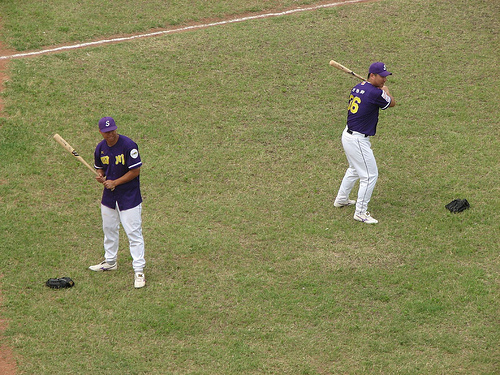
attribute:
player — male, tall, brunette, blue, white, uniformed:
[311, 52, 444, 270]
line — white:
[123, 20, 199, 63]